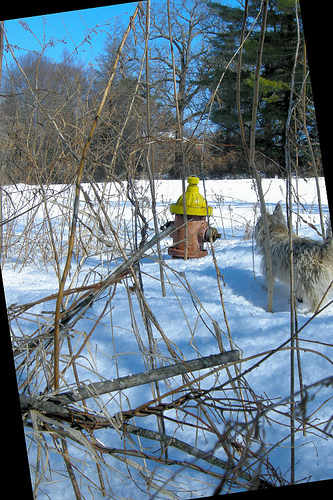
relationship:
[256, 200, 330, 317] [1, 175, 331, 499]
dog on snow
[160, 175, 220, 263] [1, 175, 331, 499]
fire hydrant in snow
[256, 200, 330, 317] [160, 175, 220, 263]
dog looking at fire hydrant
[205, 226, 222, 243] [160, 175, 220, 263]
water outlet on fire hydrant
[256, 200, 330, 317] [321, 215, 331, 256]
dog has a tail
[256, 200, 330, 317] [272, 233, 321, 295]
dog has a body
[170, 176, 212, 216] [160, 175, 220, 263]
yellow on fire hydrant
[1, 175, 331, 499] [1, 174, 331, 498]
snow on ground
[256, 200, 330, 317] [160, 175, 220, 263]
dog walking towards fire hydrant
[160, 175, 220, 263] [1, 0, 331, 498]
fire hydrant in field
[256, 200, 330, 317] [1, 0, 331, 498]
dog in field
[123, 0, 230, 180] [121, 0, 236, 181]
tree has limbs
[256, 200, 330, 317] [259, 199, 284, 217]
dog has ears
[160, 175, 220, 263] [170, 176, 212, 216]
fire hydrant part yellow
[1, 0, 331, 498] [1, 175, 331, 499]
field has snow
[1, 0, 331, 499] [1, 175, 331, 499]
sunlight on snow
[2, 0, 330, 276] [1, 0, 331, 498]
trees in field